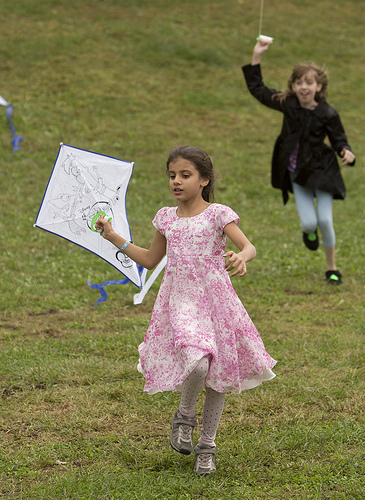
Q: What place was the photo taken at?
A: It was taken at the yard.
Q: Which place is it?
A: It is a yard.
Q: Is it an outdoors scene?
A: Yes, it is outdoors.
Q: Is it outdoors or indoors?
A: It is outdoors.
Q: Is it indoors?
A: No, it is outdoors.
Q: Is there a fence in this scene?
A: No, there are no fences.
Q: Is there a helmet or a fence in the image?
A: No, there are no fences or helmets.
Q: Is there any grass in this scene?
A: Yes, there is grass.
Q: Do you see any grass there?
A: Yes, there is grass.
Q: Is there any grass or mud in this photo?
A: Yes, there is grass.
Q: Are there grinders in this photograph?
A: No, there are no grinders.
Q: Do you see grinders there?
A: No, there are no grinders.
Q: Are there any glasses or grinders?
A: No, there are no grinders or glasses.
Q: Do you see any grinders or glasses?
A: No, there are no grinders or glasses.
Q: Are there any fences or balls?
A: No, there are no fences or balls.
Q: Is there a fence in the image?
A: No, there are no fences.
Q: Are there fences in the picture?
A: No, there are no fences.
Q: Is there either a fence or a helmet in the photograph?
A: No, there are no fences or helmets.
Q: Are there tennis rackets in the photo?
A: No, there are no tennis rackets.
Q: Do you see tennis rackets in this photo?
A: No, there are no tennis rackets.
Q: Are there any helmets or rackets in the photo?
A: No, there are no rackets or helmets.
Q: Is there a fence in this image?
A: No, there are no fences.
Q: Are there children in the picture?
A: Yes, there is a child.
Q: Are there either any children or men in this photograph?
A: Yes, there is a child.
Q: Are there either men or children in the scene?
A: Yes, there is a child.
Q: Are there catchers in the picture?
A: No, there are no catchers.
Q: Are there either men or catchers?
A: No, there are no catchers or men.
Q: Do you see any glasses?
A: No, there are no glasses.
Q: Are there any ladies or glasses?
A: No, there are no glasses or ladies.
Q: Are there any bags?
A: No, there are no bags.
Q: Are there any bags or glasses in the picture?
A: No, there are no bags or glasses.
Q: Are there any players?
A: No, there are no players.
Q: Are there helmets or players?
A: No, there are no players or helmets.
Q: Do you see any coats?
A: Yes, there is a coat.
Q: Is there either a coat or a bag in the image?
A: Yes, there is a coat.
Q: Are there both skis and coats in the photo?
A: No, there is a coat but no skis.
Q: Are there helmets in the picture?
A: No, there are no helmets.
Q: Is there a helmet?
A: No, there are no helmets.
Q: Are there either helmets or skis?
A: No, there are no helmets or skis.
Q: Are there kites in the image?
A: Yes, there is a kite.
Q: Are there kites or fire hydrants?
A: Yes, there is a kite.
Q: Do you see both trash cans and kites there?
A: No, there is a kite but no trash cans.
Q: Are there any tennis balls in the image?
A: No, there are no tennis balls.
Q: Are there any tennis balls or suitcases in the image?
A: No, there are no tennis balls or suitcases.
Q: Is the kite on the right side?
A: Yes, the kite is on the right of the image.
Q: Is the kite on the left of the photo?
A: No, the kite is on the right of the image.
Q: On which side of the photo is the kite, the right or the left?
A: The kite is on the right of the image.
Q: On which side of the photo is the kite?
A: The kite is on the right of the image.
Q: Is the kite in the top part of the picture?
A: Yes, the kite is in the top of the image.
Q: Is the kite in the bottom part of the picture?
A: No, the kite is in the top of the image.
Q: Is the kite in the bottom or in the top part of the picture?
A: The kite is in the top of the image.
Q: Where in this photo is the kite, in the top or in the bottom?
A: The kite is in the top of the image.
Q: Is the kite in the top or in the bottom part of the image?
A: The kite is in the top of the image.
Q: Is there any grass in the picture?
A: Yes, there is grass.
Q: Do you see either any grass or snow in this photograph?
A: Yes, there is grass.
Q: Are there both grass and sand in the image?
A: No, there is grass but no sand.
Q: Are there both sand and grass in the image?
A: No, there is grass but no sand.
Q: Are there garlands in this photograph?
A: No, there are no garlands.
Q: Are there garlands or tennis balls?
A: No, there are no garlands or tennis balls.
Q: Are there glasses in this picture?
A: No, there are no glasses.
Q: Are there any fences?
A: No, there are no fences.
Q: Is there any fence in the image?
A: No, there are no fences.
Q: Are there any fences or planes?
A: No, there are no fences or planes.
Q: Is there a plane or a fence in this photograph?
A: No, there are no fences or airplanes.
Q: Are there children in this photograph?
A: Yes, there is a child.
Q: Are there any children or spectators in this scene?
A: Yes, there is a child.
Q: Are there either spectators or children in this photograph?
A: Yes, there is a child.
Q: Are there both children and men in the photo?
A: No, there is a child but no men.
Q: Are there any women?
A: No, there are no women.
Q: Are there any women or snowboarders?
A: No, there are no women or snowboarders.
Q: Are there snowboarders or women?
A: No, there are no women or snowboarders.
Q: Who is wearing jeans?
A: The kid is wearing jeans.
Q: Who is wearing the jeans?
A: The kid is wearing jeans.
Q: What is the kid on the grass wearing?
A: The kid is wearing jeans.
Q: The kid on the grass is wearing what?
A: The kid is wearing jeans.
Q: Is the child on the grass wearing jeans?
A: Yes, the child is wearing jeans.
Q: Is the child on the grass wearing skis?
A: No, the kid is wearing jeans.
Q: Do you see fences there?
A: No, there are no fences.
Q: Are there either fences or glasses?
A: No, there are no fences or glasses.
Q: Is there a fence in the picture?
A: No, there are no fences.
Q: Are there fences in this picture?
A: No, there are no fences.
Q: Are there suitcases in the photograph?
A: No, there are no suitcases.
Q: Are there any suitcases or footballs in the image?
A: No, there are no suitcases or footballs.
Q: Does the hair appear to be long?
A: Yes, the hair is long.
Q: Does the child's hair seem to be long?
A: Yes, the hair is long.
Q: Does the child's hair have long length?
A: Yes, the hair is long.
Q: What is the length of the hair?
A: The hair is long.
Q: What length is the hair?
A: The hair is long.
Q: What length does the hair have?
A: The hair has long length.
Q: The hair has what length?
A: The hair is long.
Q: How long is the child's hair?
A: The hair is long.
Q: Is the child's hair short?
A: No, the hair is long.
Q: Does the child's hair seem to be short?
A: No, the hair is long.